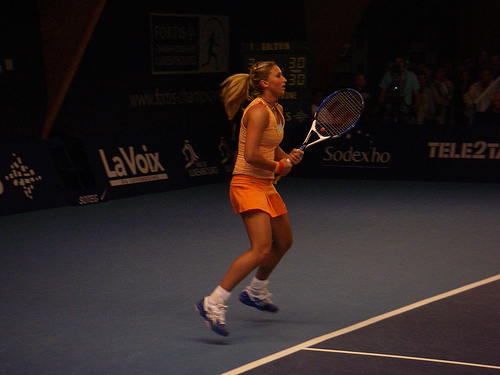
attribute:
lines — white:
[273, 319, 377, 370]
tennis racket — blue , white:
[275, 84, 366, 178]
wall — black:
[0, 107, 498, 219]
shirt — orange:
[234, 102, 283, 178]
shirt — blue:
[378, 70, 425, 113]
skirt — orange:
[226, 172, 289, 216]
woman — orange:
[192, 60, 372, 335]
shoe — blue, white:
[192, 294, 237, 342]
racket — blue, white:
[272, 85, 364, 182]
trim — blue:
[193, 295, 230, 340]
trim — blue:
[238, 290, 277, 310]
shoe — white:
[190, 291, 228, 335]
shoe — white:
[229, 287, 279, 315]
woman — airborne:
[196, 58, 290, 338]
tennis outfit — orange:
[227, 97, 287, 217]